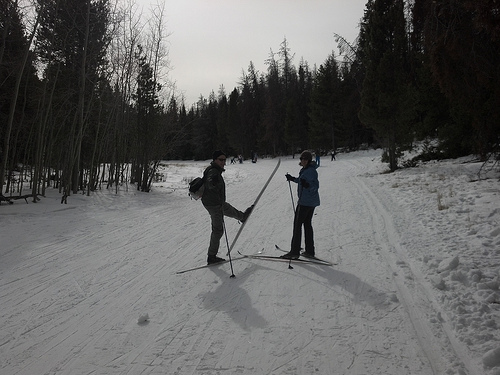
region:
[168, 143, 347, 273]
two people wearing snowboarding equipment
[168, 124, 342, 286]
two snowboarders on snow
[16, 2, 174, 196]
tall skinny bare trees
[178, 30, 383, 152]
tall leafy trees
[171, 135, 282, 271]
male wearing snowboarding equipment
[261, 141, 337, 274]
female wearing snowboarding equipment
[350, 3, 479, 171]
tall leafy green tree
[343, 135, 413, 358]
long snow trail left behind snowboarder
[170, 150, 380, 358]
snow path for snowboarders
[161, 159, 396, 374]
smooth clear path for snowboarders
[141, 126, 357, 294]
two people on a ski hill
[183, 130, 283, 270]
a person wearing skis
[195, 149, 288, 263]
a man kicking his ski in the air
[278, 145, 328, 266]
a woman in a blue jacket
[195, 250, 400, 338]
two shadows in the snow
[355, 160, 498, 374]
cross country ski tracks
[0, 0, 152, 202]
trees without leave on them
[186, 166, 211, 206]
the backpack on a man's back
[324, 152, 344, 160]
a person cross country skiing in the distance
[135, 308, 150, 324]
a chunk of ice on the snow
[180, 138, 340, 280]
man and woman on skis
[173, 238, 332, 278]
skis on feet of people on slope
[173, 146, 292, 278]
man holding ski in air on slope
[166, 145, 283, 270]
man with backpack and skis on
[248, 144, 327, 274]
woman in blue coat holding ski poles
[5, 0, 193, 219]
forest of brown trees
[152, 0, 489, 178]
forest of green evergreen trees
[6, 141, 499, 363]
snow covered ski slope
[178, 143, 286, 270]
man wearing sunglasses on ski slope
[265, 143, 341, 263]
woman wearing sunglasses and hat on ski slope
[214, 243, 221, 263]
leg of a man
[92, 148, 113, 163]
part of a forest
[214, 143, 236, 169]
face of a man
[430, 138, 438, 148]
part of a bush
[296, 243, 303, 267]
leg of a lady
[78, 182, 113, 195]
part of the stem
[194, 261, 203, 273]
part of a board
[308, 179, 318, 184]
elbow of a man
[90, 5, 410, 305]
couple posing while skiing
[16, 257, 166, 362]
marks from skis in the snow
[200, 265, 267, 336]
shadow of a skier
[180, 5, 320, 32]
gray sky in winter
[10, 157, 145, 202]
bottom of trees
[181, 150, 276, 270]
man holding one of his skis up in the air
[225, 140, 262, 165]
people further down the run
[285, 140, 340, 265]
woman on skis looks back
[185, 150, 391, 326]
two skiers and their shadows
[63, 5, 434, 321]
people enjoying winter skiing